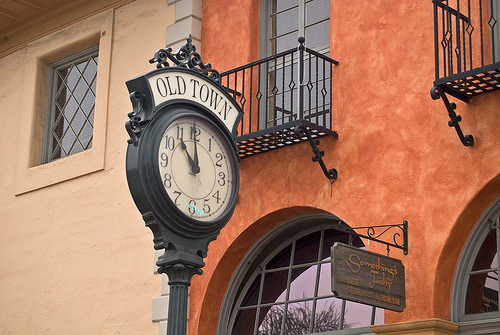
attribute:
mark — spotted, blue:
[186, 201, 206, 215]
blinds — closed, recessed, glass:
[39, 46, 100, 161]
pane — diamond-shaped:
[68, 108, 89, 137]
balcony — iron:
[429, 2, 499, 103]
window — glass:
[467, 226, 499, 311]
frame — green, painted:
[450, 197, 500, 322]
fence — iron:
[220, 36, 332, 133]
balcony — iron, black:
[215, 35, 334, 159]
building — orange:
[188, 0, 500, 334]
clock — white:
[155, 110, 238, 227]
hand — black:
[179, 136, 194, 167]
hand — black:
[191, 118, 200, 162]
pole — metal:
[156, 247, 205, 333]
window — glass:
[229, 226, 384, 332]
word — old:
[155, 75, 190, 100]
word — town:
[188, 74, 233, 121]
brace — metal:
[338, 217, 411, 254]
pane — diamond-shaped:
[62, 63, 83, 93]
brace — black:
[290, 123, 338, 181]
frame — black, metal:
[124, 104, 240, 256]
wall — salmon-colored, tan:
[1, 1, 176, 334]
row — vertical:
[151, 1, 204, 331]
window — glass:
[268, 0, 331, 126]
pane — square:
[258, 267, 291, 308]